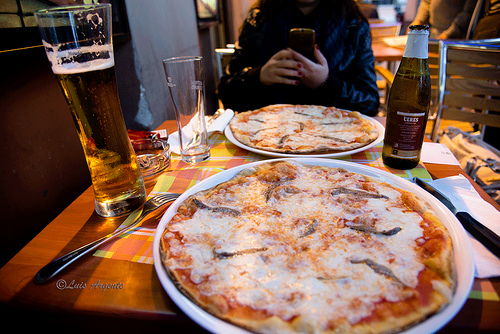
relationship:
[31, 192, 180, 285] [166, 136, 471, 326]
fork next plate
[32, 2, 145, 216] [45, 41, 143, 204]
glass has beer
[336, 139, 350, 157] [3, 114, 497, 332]
plate on table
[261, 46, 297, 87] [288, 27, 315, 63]
hand holding cell phone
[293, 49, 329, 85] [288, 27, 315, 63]
hand holding cell phone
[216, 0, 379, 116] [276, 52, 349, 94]
lady using phone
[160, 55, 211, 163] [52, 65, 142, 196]
beer glass of beer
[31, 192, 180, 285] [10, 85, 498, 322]
fork on top of table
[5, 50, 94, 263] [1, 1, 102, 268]
back of booth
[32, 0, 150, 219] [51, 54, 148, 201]
glass of beer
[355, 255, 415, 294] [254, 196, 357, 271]
anchovies on pizza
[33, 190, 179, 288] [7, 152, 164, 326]
fork on table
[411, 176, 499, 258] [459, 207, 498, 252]
knife has handle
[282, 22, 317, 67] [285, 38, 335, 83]
cell phone in hand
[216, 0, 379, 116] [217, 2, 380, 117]
lady has blue blouse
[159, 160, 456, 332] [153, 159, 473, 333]
pizza on a serving plate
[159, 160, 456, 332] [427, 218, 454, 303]
pizza has crust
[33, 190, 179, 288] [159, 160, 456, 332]
fork next to pizza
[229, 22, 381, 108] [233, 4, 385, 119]
lady wearing blue blouse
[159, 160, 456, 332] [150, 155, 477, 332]
pizza on dish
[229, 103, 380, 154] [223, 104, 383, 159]
pizza on dish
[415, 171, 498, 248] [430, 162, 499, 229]
knife on napkin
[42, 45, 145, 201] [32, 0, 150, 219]
beverage in glass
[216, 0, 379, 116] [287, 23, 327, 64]
lady using cell phone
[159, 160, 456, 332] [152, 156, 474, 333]
pizza on serving plate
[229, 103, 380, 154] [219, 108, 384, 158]
pizza on plate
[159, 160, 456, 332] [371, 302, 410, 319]
pizza has orange sauce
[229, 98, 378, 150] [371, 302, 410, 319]
pizza has orange sauce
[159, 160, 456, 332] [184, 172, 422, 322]
pizza has cheese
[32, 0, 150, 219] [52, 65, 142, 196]
glass has beer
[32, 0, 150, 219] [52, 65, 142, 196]
glass of beer